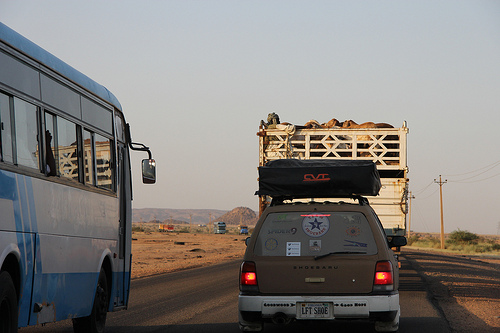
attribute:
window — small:
[38, 103, 88, 186]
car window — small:
[249, 209, 381, 259]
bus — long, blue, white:
[0, 23, 156, 332]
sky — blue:
[107, 24, 472, 109]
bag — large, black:
[258, 158, 378, 194]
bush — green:
[451, 227, 479, 248]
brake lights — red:
[373, 269, 392, 285]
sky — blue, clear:
[1, 0, 498, 235]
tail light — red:
[231, 257, 268, 295]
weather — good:
[2, 1, 497, 330]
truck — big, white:
[255, 112, 411, 270]